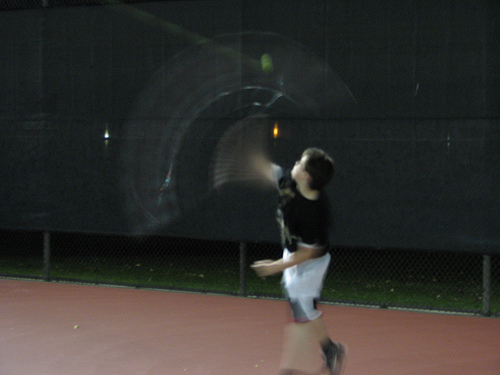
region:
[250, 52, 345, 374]
blurred image of man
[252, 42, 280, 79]
blurred image of ball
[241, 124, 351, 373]
man in black and white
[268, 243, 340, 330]
white shorts on man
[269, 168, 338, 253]
black shirt on man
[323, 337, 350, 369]
tennis shoe on man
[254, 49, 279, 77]
green ball in air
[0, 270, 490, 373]
brown ground under man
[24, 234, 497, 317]
green grass on side of man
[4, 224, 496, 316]
fence between man and grass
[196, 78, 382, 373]
Boy playing tennis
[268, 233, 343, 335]
Boy in black and white shorts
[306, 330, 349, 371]
Black shoes on man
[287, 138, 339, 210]
Boy with dark brown hair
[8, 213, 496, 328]
Grey chain link fence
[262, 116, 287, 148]
Small light in the distance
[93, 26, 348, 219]
Boy waving light in his hand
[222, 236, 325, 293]
Boys skinny white arm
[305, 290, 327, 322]
Black design on white shorts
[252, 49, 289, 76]
Small green object in thes ky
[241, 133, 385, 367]
The boy is playing with a ball on the court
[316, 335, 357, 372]
The foot of the boy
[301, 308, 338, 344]
The leg of the boy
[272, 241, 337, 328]
The boy has on white pants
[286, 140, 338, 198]
The head of the boy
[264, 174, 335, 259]
The boy has on a black shirt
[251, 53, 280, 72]
The green ball is in the air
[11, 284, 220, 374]
The ground is made of concrete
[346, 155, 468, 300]
The gate is made of metal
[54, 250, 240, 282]
The grass is short and green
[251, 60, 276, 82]
ball in the air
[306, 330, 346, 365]
foot of the player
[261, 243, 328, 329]
shorts on the player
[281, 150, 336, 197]
head of the player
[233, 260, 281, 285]
hand of the player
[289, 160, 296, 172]
nose of the player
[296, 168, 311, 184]
ear of the player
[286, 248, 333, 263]
elbow of the player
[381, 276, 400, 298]
fence around the court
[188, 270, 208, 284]
fence around the court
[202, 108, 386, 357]
This is a boy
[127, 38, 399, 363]
The boy is playing tennis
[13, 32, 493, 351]
The picture taken in the evening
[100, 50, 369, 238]
Boy rapidly swinging a tennis racket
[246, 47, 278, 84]
Tennis ball in the air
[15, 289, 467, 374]
Boy playing on a hard surface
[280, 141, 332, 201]
Boy focused on the tennis ball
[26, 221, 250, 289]
Chain link fence behind the court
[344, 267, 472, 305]
Grass on the other side of the fence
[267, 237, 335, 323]
Boy wearing white shorts